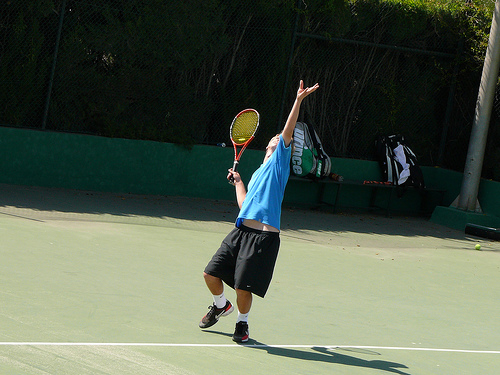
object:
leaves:
[473, 18, 477, 21]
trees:
[0, 0, 500, 180]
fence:
[0, 0, 500, 184]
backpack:
[380, 135, 427, 189]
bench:
[280, 173, 440, 214]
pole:
[448, 12, 499, 214]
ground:
[0, 185, 500, 375]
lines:
[0, 341, 500, 355]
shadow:
[199, 329, 415, 375]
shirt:
[235, 133, 292, 233]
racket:
[228, 108, 262, 184]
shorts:
[203, 222, 279, 299]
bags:
[291, 121, 331, 181]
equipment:
[301, 108, 313, 125]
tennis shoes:
[199, 298, 235, 330]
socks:
[211, 290, 227, 309]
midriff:
[242, 219, 280, 233]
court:
[0, 0, 500, 374]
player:
[198, 80, 318, 343]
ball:
[475, 244, 482, 250]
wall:
[0, 125, 500, 215]